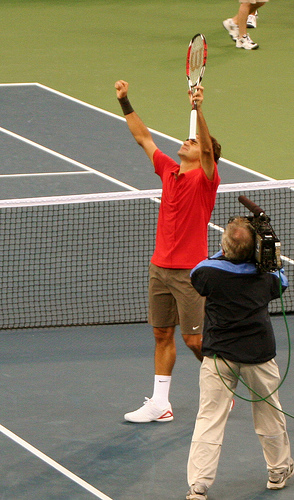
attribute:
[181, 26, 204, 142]
tennis racket — black, white, red, orange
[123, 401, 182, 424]
shoe — white, for playing, red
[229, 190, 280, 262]
video camera — black, recording action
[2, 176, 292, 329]
net — partial, black, used in matches, netting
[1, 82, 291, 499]
tennis pitch — partial, grey, gray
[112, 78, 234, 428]
man — tennis player, male, celebrating victory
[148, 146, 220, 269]
shirt — orange, red, black, blue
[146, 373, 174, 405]
sock — white, crew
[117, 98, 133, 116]
wrist band — brown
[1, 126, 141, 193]
line — white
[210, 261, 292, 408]
wire — green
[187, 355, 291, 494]
pants — khaki, beige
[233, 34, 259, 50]
sneaker — white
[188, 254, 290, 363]
shirt — black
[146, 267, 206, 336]
shorts — brown, tan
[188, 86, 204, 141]
handle — white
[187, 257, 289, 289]
stripe — blue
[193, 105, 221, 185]
arm — up in air